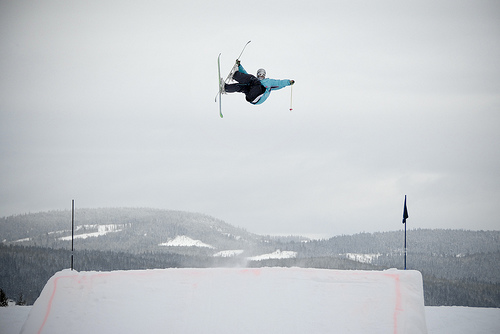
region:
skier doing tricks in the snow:
[202, 24, 302, 121]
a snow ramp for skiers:
[29, 255, 439, 331]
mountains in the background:
[13, 201, 490, 267]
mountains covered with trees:
[1, 196, 489, 261]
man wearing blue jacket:
[213, 32, 301, 122]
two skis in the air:
[209, 26, 254, 117]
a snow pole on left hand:
[283, 71, 300, 121]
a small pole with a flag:
[395, 187, 420, 269]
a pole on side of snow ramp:
[395, 188, 424, 273]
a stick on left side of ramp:
[58, 187, 88, 273]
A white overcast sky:
[360, 53, 403, 100]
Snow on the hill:
[160, 235, 200, 250]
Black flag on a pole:
[400, 197, 405, 217]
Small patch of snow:
[126, 286, 141, 302]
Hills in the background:
[146, 210, 168, 231]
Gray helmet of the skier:
[257, 67, 267, 74]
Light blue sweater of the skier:
[261, 80, 277, 85]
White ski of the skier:
[216, 57, 223, 117]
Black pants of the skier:
[238, 71, 257, 98]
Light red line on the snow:
[43, 277, 60, 319]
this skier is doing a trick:
[133, 12, 330, 148]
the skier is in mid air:
[187, 28, 409, 194]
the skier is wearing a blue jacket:
[176, 3, 313, 128]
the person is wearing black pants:
[181, 31, 311, 136]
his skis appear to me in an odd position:
[160, 27, 342, 143]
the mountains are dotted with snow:
[85, 182, 470, 283]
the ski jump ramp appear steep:
[17, 241, 447, 332]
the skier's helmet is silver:
[192, 26, 306, 129]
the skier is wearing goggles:
[226, 45, 292, 124]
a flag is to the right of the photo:
[395, 175, 422, 277]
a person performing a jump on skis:
[215, 40, 295, 122]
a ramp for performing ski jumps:
[20, 265, 427, 331]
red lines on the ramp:
[38, 266, 400, 332]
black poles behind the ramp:
[63, 192, 410, 269]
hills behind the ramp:
[0, 206, 499, 306]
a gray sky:
[1, 0, 499, 242]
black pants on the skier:
[224, 70, 264, 102]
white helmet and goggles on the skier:
[258, 68, 266, 77]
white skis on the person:
[214, 38, 253, 118]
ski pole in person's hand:
[289, 81, 294, 111]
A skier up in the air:
[178, 36, 327, 127]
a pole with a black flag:
[393, 187, 420, 279]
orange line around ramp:
[19, 265, 424, 332]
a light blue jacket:
[231, 60, 302, 115]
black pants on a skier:
[219, 69, 271, 109]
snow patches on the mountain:
[45, 210, 392, 265]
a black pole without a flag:
[63, 193, 89, 275]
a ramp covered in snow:
[11, 253, 456, 332]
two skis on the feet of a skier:
[208, 29, 259, 118]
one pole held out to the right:
[288, 76, 313, 118]